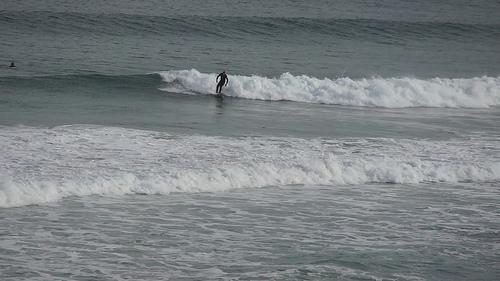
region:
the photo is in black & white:
[1, 2, 498, 279]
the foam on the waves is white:
[142, 56, 497, 102]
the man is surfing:
[205, 55, 245, 115]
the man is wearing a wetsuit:
[210, 35, 225, 130]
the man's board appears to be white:
[207, 48, 238, 116]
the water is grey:
[92, 36, 213, 61]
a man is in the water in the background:
[7, 53, 17, 84]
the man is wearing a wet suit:
[200, 63, 237, 118]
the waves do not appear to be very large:
[50, 121, 441, 197]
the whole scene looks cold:
[0, 7, 456, 271]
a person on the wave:
[197, 49, 254, 131]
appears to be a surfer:
[200, 49, 247, 131]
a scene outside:
[5, 7, 470, 278]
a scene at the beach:
[10, 6, 494, 271]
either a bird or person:
[3, 57, 25, 65]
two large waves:
[9, 51, 499, 211]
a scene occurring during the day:
[22, 9, 494, 246]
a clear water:
[30, 18, 470, 279]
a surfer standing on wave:
[203, 52, 261, 102]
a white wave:
[162, 57, 494, 103]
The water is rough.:
[5, 3, 499, 279]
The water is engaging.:
[3, 3, 498, 271]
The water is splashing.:
[5, 5, 499, 257]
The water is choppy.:
[4, 6, 497, 279]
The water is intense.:
[1, 1, 497, 277]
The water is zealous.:
[1, 1, 491, 276]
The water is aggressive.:
[0, 0, 495, 275]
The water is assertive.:
[0, 0, 495, 275]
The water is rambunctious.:
[1, 0, 496, 276]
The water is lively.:
[3, 3, 496, 278]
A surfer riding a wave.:
[198, 59, 240, 105]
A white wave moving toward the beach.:
[3, 112, 305, 199]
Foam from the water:
[158, 196, 258, 239]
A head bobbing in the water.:
[3, 56, 24, 67]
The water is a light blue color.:
[211, 5, 296, 55]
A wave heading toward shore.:
[118, 7, 408, 47]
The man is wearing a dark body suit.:
[218, 76, 234, 89]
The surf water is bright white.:
[275, 73, 453, 110]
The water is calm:
[188, 96, 255, 136]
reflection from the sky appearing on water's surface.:
[266, 107, 326, 124]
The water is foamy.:
[4, 10, 491, 279]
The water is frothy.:
[3, 8, 498, 275]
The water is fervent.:
[3, 3, 498, 272]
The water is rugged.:
[4, 4, 495, 279]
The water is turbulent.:
[2, 2, 499, 274]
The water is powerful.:
[1, 1, 496, 276]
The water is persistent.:
[2, 6, 497, 273]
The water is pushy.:
[3, 0, 498, 275]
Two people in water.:
[2, 5, 272, 162]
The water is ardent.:
[3, 4, 498, 277]